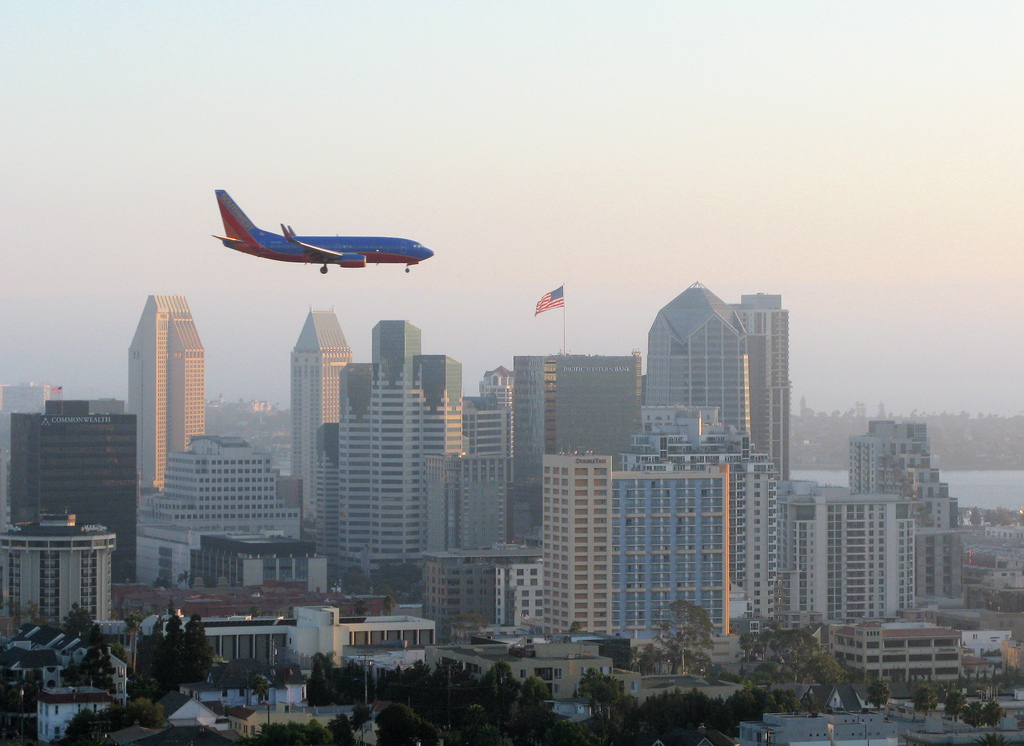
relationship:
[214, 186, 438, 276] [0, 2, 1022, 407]
plane in sky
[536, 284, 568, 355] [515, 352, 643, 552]
flag on building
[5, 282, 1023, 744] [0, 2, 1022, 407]
buildings below sky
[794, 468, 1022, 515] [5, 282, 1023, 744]
water behind buildings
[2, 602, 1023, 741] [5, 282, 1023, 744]
trees under buildings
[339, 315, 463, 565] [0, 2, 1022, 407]
building under sky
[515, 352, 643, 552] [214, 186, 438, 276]
building behind plane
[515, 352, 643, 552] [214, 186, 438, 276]
building under plane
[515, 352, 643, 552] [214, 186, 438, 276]
building on plane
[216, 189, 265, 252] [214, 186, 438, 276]
tail of plane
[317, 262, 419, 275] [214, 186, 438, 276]
gear under plane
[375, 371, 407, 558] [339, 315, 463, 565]
windows on building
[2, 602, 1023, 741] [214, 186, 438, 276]
trees under plane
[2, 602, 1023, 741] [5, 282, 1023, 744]
trees near buildings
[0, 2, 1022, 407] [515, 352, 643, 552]
sky over building